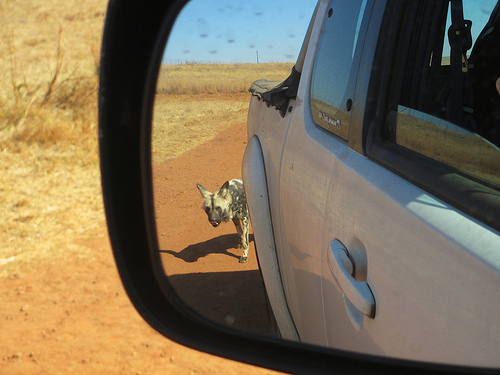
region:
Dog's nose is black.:
[208, 211, 225, 222]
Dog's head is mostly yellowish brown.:
[207, 192, 225, 206]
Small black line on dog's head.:
[206, 189, 219, 204]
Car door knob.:
[316, 220, 387, 341]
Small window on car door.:
[305, 1, 363, 132]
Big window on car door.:
[361, 0, 497, 237]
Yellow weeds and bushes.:
[8, 18, 92, 190]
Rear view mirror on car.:
[88, 4, 498, 373]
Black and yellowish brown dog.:
[181, 167, 259, 265]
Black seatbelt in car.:
[444, 0, 476, 129]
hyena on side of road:
[190, 165, 252, 262]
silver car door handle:
[317, 236, 372, 322]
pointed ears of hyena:
[188, 178, 233, 197]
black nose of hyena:
[206, 210, 222, 227]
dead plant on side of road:
[11, 67, 81, 160]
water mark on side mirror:
[189, 20, 296, 80]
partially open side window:
[388, 106, 494, 185]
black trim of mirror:
[92, 169, 162, 236]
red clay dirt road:
[36, 290, 90, 326]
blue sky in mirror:
[215, 13, 297, 58]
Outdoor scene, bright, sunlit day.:
[3, 7, 498, 364]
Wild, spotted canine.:
[201, 163, 259, 273]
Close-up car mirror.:
[103, 2, 498, 374]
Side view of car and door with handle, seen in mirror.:
[234, 10, 499, 372]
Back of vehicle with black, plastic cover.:
[251, 0, 325, 116]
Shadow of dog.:
[167, 233, 254, 277]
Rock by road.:
[9, 10, 96, 228]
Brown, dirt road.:
[21, 268, 133, 368]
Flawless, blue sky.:
[198, 10, 272, 62]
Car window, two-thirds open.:
[364, 0, 499, 213]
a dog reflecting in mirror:
[188, 155, 258, 265]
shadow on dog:
[161, 228, 233, 275]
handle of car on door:
[316, 233, 382, 325]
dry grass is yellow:
[12, 10, 104, 234]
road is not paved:
[9, 258, 146, 373]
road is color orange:
[14, 259, 118, 373]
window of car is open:
[386, 5, 499, 168]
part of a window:
[386, 113, 493, 190]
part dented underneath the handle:
[328, 231, 388, 336]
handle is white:
[315, 234, 384, 326]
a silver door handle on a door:
[322, 235, 373, 313]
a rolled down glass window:
[388, 98, 498, 200]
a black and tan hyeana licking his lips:
[196, 178, 252, 259]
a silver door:
[287, 2, 499, 374]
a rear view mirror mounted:
[97, 1, 497, 373]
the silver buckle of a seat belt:
[458, 52, 470, 73]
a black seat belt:
[450, 2, 471, 124]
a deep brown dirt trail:
[155, 120, 280, 332]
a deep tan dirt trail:
[5, 232, 267, 374]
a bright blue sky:
[157, 1, 320, 71]